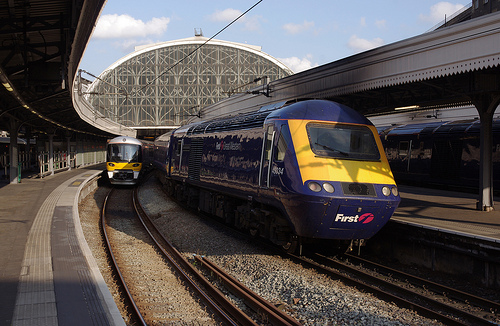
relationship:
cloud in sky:
[89, 10, 173, 39] [87, 0, 427, 43]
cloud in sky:
[89, 10, 174, 41] [56, 0, 476, 80]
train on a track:
[153, 97, 402, 256] [297, 245, 499, 326]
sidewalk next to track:
[0, 170, 121, 322] [101, 185, 276, 324]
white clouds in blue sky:
[276, 54, 318, 75] [72, 2, 470, 79]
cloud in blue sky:
[207, 4, 245, 23] [72, 2, 470, 79]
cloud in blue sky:
[89, 10, 173, 39] [72, 2, 470, 79]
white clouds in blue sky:
[348, 35, 381, 53] [72, 2, 470, 79]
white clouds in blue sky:
[419, 2, 473, 27] [72, 2, 470, 79]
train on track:
[153, 97, 402, 256] [297, 245, 499, 324]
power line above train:
[123, 39, 303, 70] [153, 97, 402, 256]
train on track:
[153, 97, 402, 256] [101, 185, 498, 325]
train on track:
[153, 97, 402, 256] [327, 254, 480, 313]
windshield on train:
[301, 118, 383, 165] [145, 88, 405, 260]